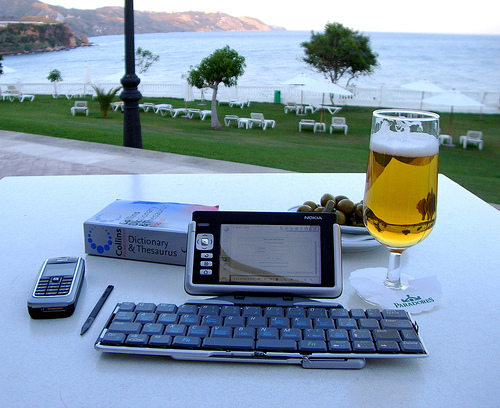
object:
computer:
[94, 210, 429, 367]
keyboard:
[93, 300, 428, 368]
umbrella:
[294, 79, 354, 124]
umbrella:
[278, 75, 316, 115]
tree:
[299, 20, 381, 104]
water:
[0, 29, 499, 112]